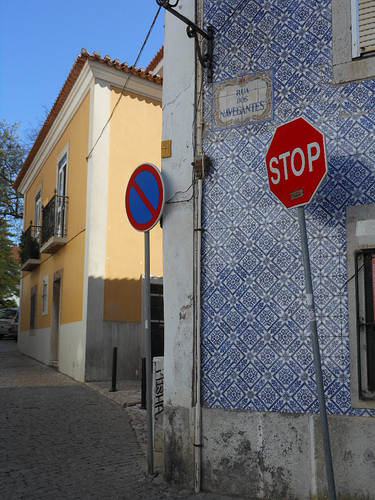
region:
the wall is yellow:
[125, 128, 148, 177]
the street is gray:
[65, 447, 102, 478]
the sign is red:
[240, 109, 328, 229]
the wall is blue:
[223, 215, 258, 314]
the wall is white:
[57, 329, 109, 361]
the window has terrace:
[33, 154, 99, 277]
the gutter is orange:
[40, 63, 77, 96]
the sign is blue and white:
[111, 154, 181, 255]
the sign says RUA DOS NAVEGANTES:
[205, 64, 296, 144]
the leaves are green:
[5, 236, 18, 290]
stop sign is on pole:
[260, 114, 329, 213]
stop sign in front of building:
[162, 4, 374, 498]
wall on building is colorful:
[200, 3, 374, 417]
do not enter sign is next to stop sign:
[124, 164, 164, 231]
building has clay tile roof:
[4, 51, 166, 193]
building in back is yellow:
[6, 61, 191, 386]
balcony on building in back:
[35, 144, 66, 252]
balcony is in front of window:
[30, 191, 73, 252]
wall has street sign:
[208, 69, 278, 127]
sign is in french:
[211, 76, 279, 128]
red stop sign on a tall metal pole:
[262, 112, 347, 498]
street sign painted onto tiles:
[208, 68, 278, 131]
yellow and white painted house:
[10, 138, 163, 389]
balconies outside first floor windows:
[16, 192, 67, 271]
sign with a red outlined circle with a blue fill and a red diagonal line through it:
[118, 160, 168, 233]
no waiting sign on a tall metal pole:
[121, 159, 171, 480]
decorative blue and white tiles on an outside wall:
[196, 0, 373, 410]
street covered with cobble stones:
[1, 345, 202, 499]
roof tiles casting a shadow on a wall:
[88, 52, 165, 106]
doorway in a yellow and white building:
[46, 268, 63, 369]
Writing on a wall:
[150, 358, 174, 416]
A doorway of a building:
[39, 274, 76, 379]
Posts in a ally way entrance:
[108, 345, 125, 402]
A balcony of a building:
[16, 210, 42, 267]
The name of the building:
[211, 73, 283, 127]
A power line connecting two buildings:
[69, 2, 232, 178]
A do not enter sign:
[113, 161, 181, 249]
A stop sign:
[257, 113, 342, 205]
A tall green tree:
[1, 120, 19, 344]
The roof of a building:
[19, 24, 178, 199]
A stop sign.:
[247, 108, 367, 335]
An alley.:
[94, 63, 162, 401]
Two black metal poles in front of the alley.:
[105, 326, 151, 416]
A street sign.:
[112, 159, 176, 480]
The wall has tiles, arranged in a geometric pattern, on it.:
[199, 4, 334, 297]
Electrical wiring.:
[173, 145, 213, 478]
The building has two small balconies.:
[15, 160, 75, 269]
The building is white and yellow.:
[23, 91, 143, 376]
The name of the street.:
[203, 66, 279, 141]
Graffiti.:
[150, 364, 165, 424]